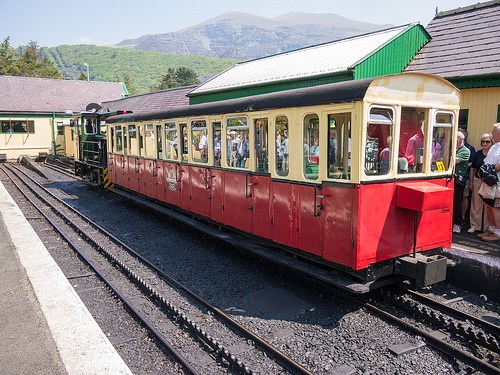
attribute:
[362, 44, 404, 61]
building — green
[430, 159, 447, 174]
sign — yellow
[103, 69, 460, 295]
train car — red, beige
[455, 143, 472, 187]
shirt — green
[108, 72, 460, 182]
top — beige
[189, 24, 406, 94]
roof — white